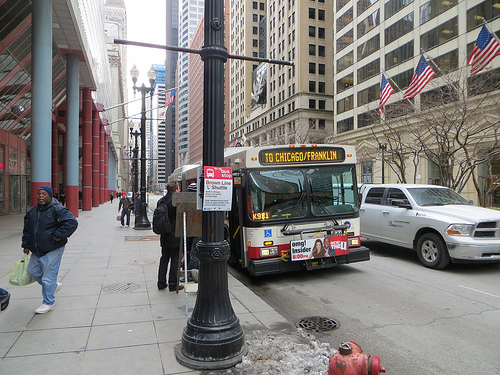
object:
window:
[370, 8, 381, 28]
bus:
[165, 144, 370, 287]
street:
[142, 193, 499, 374]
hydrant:
[322, 339, 384, 374]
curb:
[226, 273, 302, 332]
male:
[20, 186, 76, 315]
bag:
[7, 249, 43, 286]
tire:
[413, 230, 450, 269]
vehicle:
[355, 184, 498, 270]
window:
[387, 188, 412, 209]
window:
[364, 185, 384, 206]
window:
[404, 185, 474, 207]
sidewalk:
[0, 189, 318, 375]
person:
[113, 191, 135, 228]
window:
[406, 38, 414, 61]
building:
[330, 0, 499, 214]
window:
[373, 56, 381, 76]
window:
[360, 65, 366, 82]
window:
[308, 25, 315, 40]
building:
[227, 0, 333, 148]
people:
[155, 180, 185, 294]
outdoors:
[0, 188, 498, 375]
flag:
[401, 53, 438, 103]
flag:
[465, 25, 499, 77]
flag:
[372, 71, 397, 114]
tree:
[356, 51, 500, 209]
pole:
[170, 0, 250, 371]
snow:
[220, 328, 336, 374]